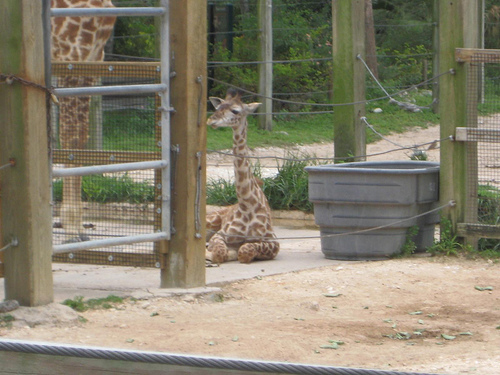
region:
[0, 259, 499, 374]
gray, dusty dirt ground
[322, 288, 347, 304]
small grey stone laying in the dirt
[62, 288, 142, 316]
clumps of weeds growing from the cement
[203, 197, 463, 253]
chain fence spanning two wooden posts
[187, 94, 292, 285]
giraffe laying down in an enclosure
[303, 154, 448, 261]
large blue container sitting beside giraffe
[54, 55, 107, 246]
long spindly legs of a giraffe standing up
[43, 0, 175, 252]
gray metal gate of giraffe enclosure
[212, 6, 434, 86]
trees with lush green leaves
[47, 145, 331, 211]
tall green grass growing in giraffe enclosure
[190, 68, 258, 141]
head of a giraffe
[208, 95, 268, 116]
ear of a giraffe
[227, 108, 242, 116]
eyes of a giraffe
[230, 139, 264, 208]
neck of a giraffe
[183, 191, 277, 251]
body of a giraffe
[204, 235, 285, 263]
legs of a giraffe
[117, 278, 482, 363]
leaves on a ground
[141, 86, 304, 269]
giraffe sitting on ground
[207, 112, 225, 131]
mouth of a giraffe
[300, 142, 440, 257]
a plastic container on the ground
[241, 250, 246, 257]
The left knee of a giraffe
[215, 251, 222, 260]
The right knee of a giraffe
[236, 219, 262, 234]
A giraffe lying down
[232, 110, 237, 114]
The eye of a giraffe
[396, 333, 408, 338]
Greens on the ground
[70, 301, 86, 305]
Bits of grass growing on the edge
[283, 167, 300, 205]
Green grass on the fence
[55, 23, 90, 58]
A big giraffe standing up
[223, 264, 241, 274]
Part of the concrete floor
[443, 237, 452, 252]
Weeds next to the fence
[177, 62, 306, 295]
the giraffe is a baby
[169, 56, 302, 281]
the giraffe is brown and white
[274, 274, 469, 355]
the dirt is light brown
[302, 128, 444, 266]
a grey bin to the right of the giraffe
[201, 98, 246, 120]
the eyes are open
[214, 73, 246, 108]
the giraffe has horns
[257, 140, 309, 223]
the grass is behind the giraffe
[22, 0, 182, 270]
the gate door is closed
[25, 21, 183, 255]
the gate door is grey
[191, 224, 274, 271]
the giraffes feet are folded under